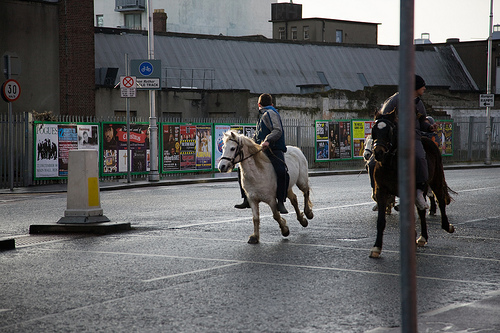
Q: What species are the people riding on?
A: Horses.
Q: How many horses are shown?
A: Two.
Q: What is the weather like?
A: Cloudy.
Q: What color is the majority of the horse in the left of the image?
A: White.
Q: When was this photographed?
A: Day time.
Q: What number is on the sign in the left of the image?
A: 30.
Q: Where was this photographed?
A: Street.